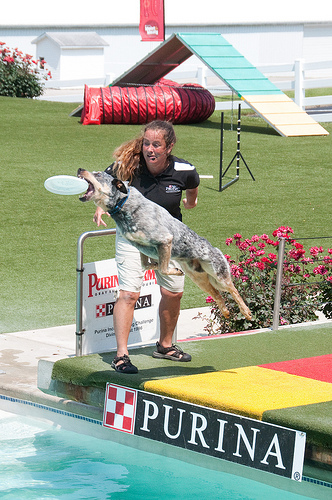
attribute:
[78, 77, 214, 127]
tube — large , hallow , plastic 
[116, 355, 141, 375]
sandals — black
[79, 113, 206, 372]
lady — blonde, standing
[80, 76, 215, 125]
dog tunnel — red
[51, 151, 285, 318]
dog — jumping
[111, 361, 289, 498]
letter — white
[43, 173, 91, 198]
white frisbee — white 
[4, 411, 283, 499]
pool — small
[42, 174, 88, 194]
frisbee — white, mid flight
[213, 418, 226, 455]
letter i — white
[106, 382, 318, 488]
sign — black, red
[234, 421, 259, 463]
n — white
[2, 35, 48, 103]
bush — large 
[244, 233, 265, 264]
flowers — red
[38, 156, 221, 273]
dog — jumping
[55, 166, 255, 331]
dog — jumping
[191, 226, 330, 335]
flower — red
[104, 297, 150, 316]
purina — white